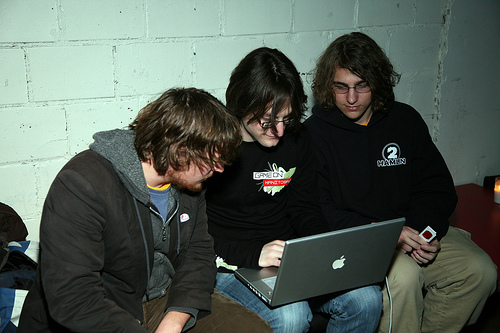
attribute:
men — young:
[62, 24, 497, 332]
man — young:
[39, 93, 235, 332]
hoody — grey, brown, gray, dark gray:
[52, 129, 225, 332]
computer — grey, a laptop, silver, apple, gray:
[234, 212, 407, 309]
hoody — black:
[308, 100, 457, 254]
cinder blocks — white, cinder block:
[2, 1, 498, 179]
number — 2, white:
[383, 145, 401, 160]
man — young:
[205, 48, 384, 330]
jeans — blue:
[217, 267, 383, 332]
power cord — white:
[375, 275, 396, 332]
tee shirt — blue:
[147, 183, 176, 223]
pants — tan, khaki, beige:
[376, 224, 498, 332]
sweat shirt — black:
[202, 131, 336, 268]